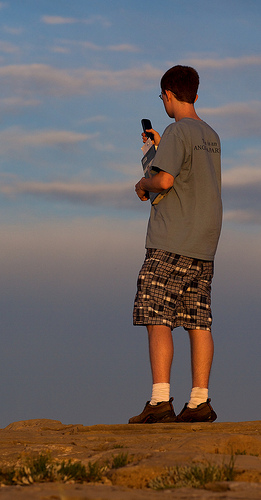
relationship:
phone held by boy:
[141, 118, 154, 143] [128, 64, 222, 424]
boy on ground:
[128, 64, 222, 424] [1, 418, 260, 498]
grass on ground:
[1, 453, 248, 484] [1, 418, 260, 498]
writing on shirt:
[192, 138, 218, 154] [145, 119, 223, 260]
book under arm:
[140, 142, 170, 206] [135, 124, 181, 201]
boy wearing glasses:
[128, 64, 222, 424] [158, 92, 164, 100]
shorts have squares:
[131, 248, 214, 331] [131, 250, 213, 330]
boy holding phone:
[128, 64, 222, 424] [141, 118, 154, 143]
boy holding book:
[128, 64, 222, 424] [140, 142, 170, 206]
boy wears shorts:
[128, 64, 222, 424] [131, 248, 214, 331]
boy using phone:
[128, 64, 222, 424] [141, 118, 154, 143]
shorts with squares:
[131, 248, 214, 331] [131, 250, 213, 330]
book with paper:
[140, 142, 170, 206] [140, 137, 153, 155]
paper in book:
[140, 137, 153, 155] [140, 142, 170, 206]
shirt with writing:
[145, 119, 223, 260] [192, 138, 218, 154]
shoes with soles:
[129, 397, 217, 423] [129, 408, 217, 422]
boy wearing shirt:
[128, 64, 222, 424] [145, 119, 223, 260]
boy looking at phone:
[128, 64, 222, 424] [141, 118, 154, 143]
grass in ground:
[1, 453, 248, 484] [1, 418, 260, 498]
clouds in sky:
[3, 15, 259, 214] [1, 1, 260, 423]